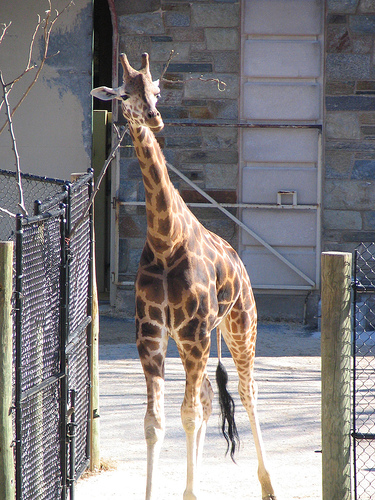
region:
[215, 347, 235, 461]
tail end of giraffe in pen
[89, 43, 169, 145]
head of giraffe in pen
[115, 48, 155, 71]
horns on giraffe in pen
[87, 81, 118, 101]
ear of the giraffe in pen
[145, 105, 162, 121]
nose of the giraffe in pen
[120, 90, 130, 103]
enclosed giraffe's right eye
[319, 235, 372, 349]
part of the fence enclosing giraffe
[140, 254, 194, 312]
chest pattern of giraffe in pen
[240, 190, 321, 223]
bar on door in giraffe pen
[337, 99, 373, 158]
part of building in giraffe enclosure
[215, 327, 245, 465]
a giraffes black tail.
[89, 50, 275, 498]
A tall brown giraffe.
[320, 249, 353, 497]
A long brown pole.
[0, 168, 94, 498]
a chain link fence.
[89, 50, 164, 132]
a giraffes head and horns.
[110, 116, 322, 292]
an old rusted gate.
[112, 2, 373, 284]
An old brick wall.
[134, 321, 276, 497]
a giraffes four legs.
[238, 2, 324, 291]
A ladder on the wall.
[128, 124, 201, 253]
a giraffes long neck.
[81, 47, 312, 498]
giraffe standing by gate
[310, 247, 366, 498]
wooden pole attached to fence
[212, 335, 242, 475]
tail of a giraffe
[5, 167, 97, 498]
black chain link fence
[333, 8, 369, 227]
stone wall of a building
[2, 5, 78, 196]
brown bare tree branches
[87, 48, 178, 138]
head of a giraffe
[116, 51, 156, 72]
horns of a giraffe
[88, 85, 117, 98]
right ear of a giraffe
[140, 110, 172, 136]
nose and mouth of a giraffe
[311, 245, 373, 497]
Wooden fence post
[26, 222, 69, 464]
Chain link fence door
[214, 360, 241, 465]
Black end of a giraffe's tail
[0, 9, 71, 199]
Wooden limbs of a tree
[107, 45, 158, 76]
Two horns of a giraffe's head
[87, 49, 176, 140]
Giraffe's head facing forward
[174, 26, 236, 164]
Different colored bricks on a wall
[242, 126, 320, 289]
Metal window in brick wall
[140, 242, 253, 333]
Spots on a giraffe's body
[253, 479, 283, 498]
One giraffe hoof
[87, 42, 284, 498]
Giraffe in the zoo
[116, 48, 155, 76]
Brown horns of giraffe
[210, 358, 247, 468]
Black tuft of giraffe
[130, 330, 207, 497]
Front legs of giraffe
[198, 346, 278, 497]
Back legs of giraffe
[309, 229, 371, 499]
Fence of wire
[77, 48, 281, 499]
Giraffe has dark brown spots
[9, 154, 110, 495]
Fence on left side of giraffe pen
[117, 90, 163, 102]
Eyes are black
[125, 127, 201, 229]
Long neck of giraffe